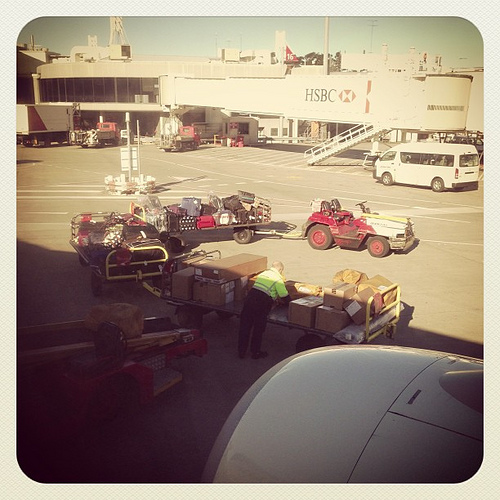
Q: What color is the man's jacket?
A: Green.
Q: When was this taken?
A: During the day.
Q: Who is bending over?
A: The man.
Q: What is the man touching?
A: Boxes.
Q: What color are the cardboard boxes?
A: Brown.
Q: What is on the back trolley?
A: Luggage.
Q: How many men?
A: One.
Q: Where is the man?
A: Tarmac.